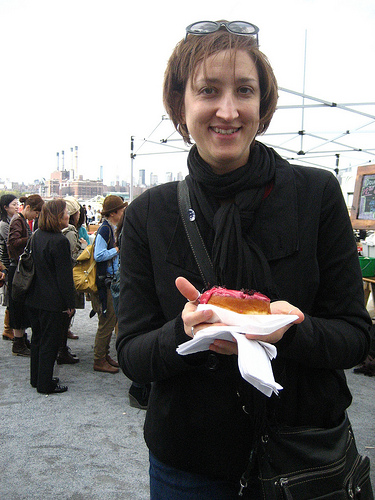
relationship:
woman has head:
[86, 13, 371, 457] [111, 10, 311, 174]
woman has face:
[86, 13, 371, 457] [173, 64, 263, 158]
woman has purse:
[86, 13, 371, 457] [267, 402, 357, 483]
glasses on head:
[186, 5, 267, 44] [111, 10, 311, 174]